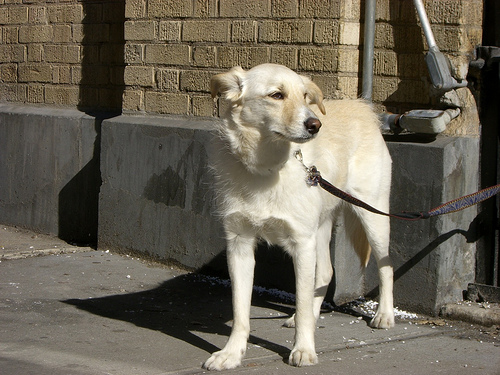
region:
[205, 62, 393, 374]
Light colored dog on a leash.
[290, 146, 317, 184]
Metal clasp of the leash that hooks to collar.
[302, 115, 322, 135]
Dark nose on light colored dog.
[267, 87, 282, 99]
Right eye on light colored dog.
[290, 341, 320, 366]
Left paw of light colored paw.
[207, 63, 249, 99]
Right light colored ear of a dog.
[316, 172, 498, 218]
Leash that is attached to a dog.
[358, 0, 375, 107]
Metal pole going up building.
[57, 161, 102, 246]
Shadow of the building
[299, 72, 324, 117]
Left ear of a light colored dog.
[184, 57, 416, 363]
large white dog with leash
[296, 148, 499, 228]
grey leash attached to dog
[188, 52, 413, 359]
white dog waiting for owner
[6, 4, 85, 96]
wall made of tan brick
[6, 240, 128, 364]
stained and dirty concrete sidewalk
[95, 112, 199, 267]
grey concrete foundation for wall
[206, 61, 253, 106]
right ear of a large white dog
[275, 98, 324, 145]
nose of a large white dog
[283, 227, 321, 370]
front left leg of a dog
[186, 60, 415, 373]
large white dog tied up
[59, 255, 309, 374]
Shadow on the pavement.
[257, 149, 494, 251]
Silver and fabric dog leash.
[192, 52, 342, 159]
The head of a dog.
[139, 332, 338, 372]
Two white dog paws.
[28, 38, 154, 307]
Shadow on the side of a building.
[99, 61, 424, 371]
Dog standing on sidewalk.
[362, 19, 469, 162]
Electricity pipes on side of building.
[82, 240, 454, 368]
Small white rocks on sidewalk.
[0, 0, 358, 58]
Tan bricks on side of building.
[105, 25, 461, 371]
dog outside of building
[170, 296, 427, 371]
four paws on pavement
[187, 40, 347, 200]
dog with head turned sideways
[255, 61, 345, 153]
round and brown nose of dog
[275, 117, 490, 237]
dark leash attached to dog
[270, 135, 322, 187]
clasp attaching leash to collar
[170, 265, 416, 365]
white pellets on sidewalk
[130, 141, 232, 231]
dark stain against wall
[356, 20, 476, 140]
pipes attached to metal boxes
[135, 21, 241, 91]
light-colored bricks on wall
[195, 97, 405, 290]
Dog standing on sidewalk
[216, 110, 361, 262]
Dog is cream color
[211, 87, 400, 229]
Dog has dark leash on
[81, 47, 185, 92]
Tan brick building behind dog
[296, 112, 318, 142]
Dog has black nose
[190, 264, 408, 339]
Dog has four legs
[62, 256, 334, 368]
Sidewalk is gray concrete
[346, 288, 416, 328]
White stuff on ground by dog's paw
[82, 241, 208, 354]
Dog's shadow to the left of dog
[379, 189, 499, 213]
Dog's leash has red edging